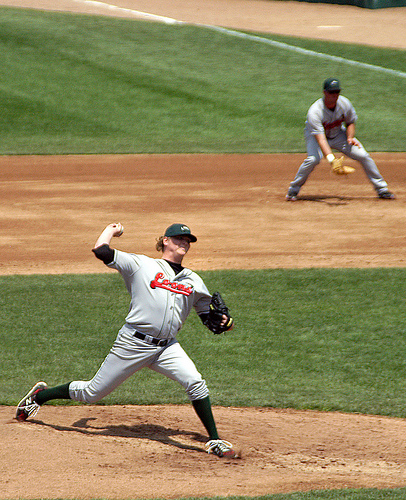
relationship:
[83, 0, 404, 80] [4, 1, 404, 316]
white line on field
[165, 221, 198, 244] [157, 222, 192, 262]
hat on head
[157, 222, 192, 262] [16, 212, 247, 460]
head on man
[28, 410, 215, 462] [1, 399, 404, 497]
shadow on dirt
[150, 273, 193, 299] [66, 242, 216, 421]
writing on uniform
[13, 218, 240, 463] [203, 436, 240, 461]
man has foot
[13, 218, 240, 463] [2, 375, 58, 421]
man has foot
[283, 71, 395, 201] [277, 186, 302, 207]
player has foot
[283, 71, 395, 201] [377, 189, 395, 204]
player has foot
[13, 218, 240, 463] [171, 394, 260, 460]
man has foot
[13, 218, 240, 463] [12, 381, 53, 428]
man has foot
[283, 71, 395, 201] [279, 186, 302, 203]
player has foot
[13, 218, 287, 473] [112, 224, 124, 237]
man getting ready to throw baseball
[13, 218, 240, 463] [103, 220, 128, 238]
man throwing ball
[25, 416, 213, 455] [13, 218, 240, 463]
shadow of man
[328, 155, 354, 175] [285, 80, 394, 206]
mitt of player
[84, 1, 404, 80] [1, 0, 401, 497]
white line on field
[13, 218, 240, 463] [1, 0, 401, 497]
man on field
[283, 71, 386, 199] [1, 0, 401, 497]
player on field